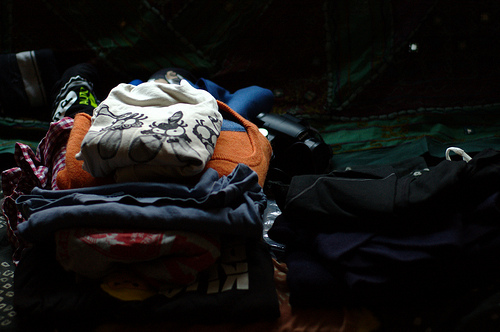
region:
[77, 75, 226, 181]
a silly white and black tshirt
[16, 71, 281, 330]
a pile of folded clothes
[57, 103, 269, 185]
a orange light sweater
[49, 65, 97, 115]
a crumpled up white, green, and black shirt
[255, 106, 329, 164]
a black video camera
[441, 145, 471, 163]
a white string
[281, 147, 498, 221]
a black pair of swim trunks with a white sting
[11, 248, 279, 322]
a black shirt with white writing on it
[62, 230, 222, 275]
a red and white shirt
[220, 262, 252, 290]
the letter K in white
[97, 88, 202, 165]
this is a clothe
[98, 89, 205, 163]
the clothe is folded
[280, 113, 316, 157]
this is a bottle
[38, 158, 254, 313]
the clothes are in a pile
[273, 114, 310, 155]
the bottle is black in color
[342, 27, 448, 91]
this is a bag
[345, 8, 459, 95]
the bag is black in color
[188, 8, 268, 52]
the room is dark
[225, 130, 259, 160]
the blouse is orange in color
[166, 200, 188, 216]
this is a jeans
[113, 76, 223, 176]
white graphic tshirt on top of pile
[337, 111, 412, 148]
green shirt on top of pile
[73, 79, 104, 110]
green portion of design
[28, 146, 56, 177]
red and grey stripe on shirt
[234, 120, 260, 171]
orange shirt in pile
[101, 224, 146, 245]
red and grey design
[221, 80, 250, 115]
blue cloth on pile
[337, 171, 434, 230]
dark black shirt on right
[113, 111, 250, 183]
casrtoon bug on white tshirt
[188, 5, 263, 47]
dark black area in back of photo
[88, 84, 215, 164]
The white shirt on the pile.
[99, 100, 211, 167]
The design on the white shirt.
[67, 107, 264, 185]
The orange shirt on the pile.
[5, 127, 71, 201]
The small red plaid shirt on the left.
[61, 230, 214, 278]
The red shirt on the pile.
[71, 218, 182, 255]
The gray design on the red shirt.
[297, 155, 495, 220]
The black shirt on the right.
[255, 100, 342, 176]
The camera next to the pile of shirts.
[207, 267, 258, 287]
The white lettering on the shirt on the bottom.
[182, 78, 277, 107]
The blue shirt next to the camera.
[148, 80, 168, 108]
part of a cloth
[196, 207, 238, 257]
edge of a towel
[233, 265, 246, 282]
part of a letter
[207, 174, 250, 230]
part of a cloth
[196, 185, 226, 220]
edge of a cloth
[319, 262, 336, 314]
part of a cloth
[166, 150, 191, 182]
edge of a cloth